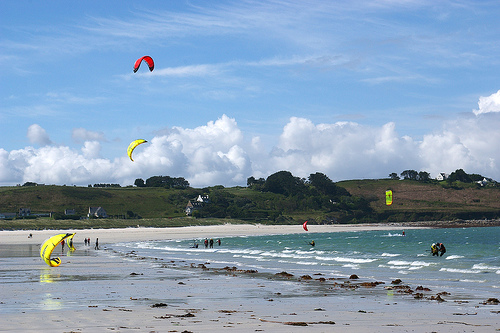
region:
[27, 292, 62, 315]
water on the sand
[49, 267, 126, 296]
wet sand on the shore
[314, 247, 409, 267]
white waves in water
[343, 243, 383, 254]
rough blue water in the ocean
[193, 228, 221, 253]
people standing in the water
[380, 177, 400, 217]
yellow kite in the air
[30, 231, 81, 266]
yellow kite on the water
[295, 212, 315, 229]
red kite in the air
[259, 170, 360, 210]
trees on the shore line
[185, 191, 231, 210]
house on the hill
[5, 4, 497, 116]
thin clouds in sky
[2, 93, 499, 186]
white puffy clouds low in sky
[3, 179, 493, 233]
grassy hill on horizon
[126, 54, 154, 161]
two floating parasails over shore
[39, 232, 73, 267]
yellow parasail on sand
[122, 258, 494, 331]
piles of seaweed on ground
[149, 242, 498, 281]
white caps of crashed waves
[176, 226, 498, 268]
surface of ocean water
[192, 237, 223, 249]
people standing in water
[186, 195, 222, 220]
house with view of water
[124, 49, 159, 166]
two kites in the sky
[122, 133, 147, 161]
yellow kite in air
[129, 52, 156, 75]
red kite in air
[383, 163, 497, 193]
trees on a hilltop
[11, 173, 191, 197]
trees on a hilltp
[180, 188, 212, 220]
house in the distance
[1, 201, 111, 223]
buildings in the background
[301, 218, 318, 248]
person flyig kite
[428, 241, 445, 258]
people standing in water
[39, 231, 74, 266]
yellow and blue glider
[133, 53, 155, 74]
red and black glider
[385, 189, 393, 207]
yellow and green glider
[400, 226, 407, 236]
person water skiing in water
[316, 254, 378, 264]
smallwave in water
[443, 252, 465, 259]
white cap in water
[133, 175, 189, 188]
trees with green leaves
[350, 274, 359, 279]
rock on shore line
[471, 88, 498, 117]
white cloud in sky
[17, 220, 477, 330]
beach strewn with seaweed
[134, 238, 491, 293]
whitecap waves approaching beach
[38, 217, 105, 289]
yellow parasail on beach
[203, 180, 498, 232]
grass covered hill above beach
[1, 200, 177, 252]
buildings by sandy beach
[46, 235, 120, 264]
people walking on beach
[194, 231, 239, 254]
people standing in surf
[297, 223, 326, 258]
person with red sail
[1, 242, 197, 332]
water on beach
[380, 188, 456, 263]
people with yellow sail in air